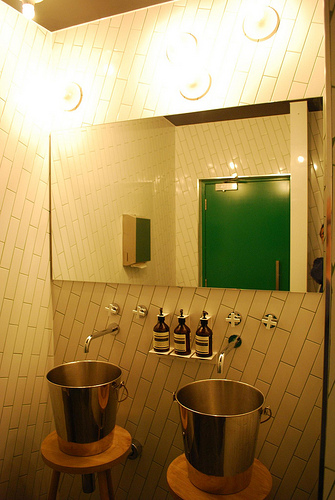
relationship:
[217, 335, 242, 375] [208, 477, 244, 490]
faucet on wall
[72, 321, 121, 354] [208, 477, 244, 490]
faucet on wall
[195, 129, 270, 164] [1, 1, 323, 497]
tile on wall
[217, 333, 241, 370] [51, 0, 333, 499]
faucet from wall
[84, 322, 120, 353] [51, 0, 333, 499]
faucet from wall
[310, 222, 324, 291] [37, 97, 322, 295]
person in mirror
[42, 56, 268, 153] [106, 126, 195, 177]
lights on wall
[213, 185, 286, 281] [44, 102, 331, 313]
green door reflecting on mirror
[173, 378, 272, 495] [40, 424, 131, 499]
bucket on stool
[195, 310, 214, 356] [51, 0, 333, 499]
bottle hanging from wall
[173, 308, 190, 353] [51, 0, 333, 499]
bottle hanging from wall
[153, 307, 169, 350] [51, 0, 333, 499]
bottle hanging from wall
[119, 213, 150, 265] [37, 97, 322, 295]
dispenser reflecting from mirror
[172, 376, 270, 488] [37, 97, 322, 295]
sinks under mirror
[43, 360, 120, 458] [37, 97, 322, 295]
sinks under mirror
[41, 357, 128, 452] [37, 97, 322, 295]
bucket under mirror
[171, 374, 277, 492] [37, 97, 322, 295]
bucket under mirror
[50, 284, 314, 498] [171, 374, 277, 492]
tile displayed behind bucket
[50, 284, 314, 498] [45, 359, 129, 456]
tile displayed behind bucket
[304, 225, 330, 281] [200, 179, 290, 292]
reflection in green door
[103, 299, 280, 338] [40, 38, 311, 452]
knobs on wall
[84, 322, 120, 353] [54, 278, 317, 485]
faucet on wall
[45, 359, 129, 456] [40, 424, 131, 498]
bucket on stool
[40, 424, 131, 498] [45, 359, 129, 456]
stool with bucket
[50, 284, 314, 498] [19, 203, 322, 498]
tile on wall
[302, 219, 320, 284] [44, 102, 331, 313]
reflection in mirror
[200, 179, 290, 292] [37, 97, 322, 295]
green door in mirror